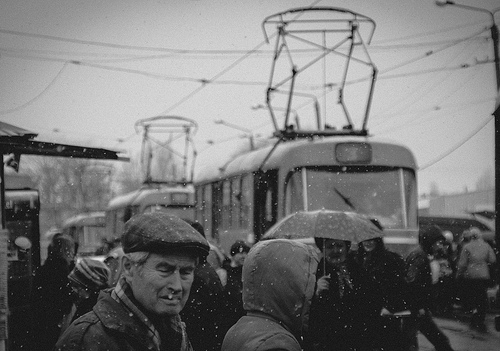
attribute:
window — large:
[299, 162, 409, 234]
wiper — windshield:
[332, 178, 391, 223]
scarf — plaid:
[110, 275, 186, 349]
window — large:
[292, 168, 424, 232]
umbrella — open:
[239, 174, 376, 250]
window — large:
[207, 183, 229, 241]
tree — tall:
[98, 162, 122, 219]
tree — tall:
[70, 155, 96, 214]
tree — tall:
[56, 160, 79, 217]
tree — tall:
[42, 157, 62, 212]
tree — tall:
[112, 149, 142, 194]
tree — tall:
[24, 155, 43, 208]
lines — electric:
[316, 7, 456, 105]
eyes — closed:
[146, 256, 193, 287]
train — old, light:
[185, 93, 440, 292]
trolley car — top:
[191, 135, 420, 277]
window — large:
[237, 171, 251, 229]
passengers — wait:
[6, 199, 493, 348]